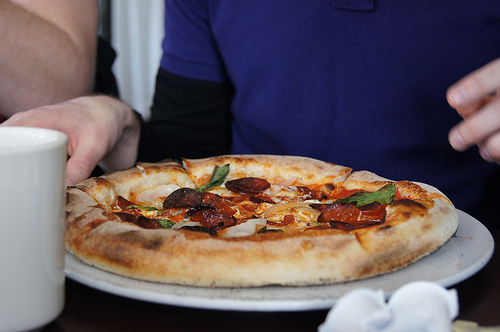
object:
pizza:
[66, 154, 459, 288]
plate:
[64, 208, 495, 312]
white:
[396, 298, 448, 332]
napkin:
[318, 280, 459, 331]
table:
[0, 208, 500, 332]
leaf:
[332, 183, 396, 207]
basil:
[193, 163, 230, 192]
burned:
[65, 208, 164, 268]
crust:
[64, 155, 458, 288]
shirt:
[133, 1, 500, 211]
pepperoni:
[225, 177, 271, 195]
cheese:
[271, 184, 297, 197]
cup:
[0, 125, 69, 332]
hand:
[0, 95, 128, 187]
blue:
[160, 0, 500, 210]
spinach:
[158, 219, 177, 229]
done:
[389, 198, 427, 208]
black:
[132, 66, 230, 167]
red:
[318, 201, 386, 229]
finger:
[66, 136, 109, 187]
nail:
[449, 128, 467, 152]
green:
[198, 163, 231, 192]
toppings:
[163, 187, 237, 230]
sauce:
[156, 208, 191, 223]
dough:
[134, 181, 169, 195]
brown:
[0, 211, 500, 332]